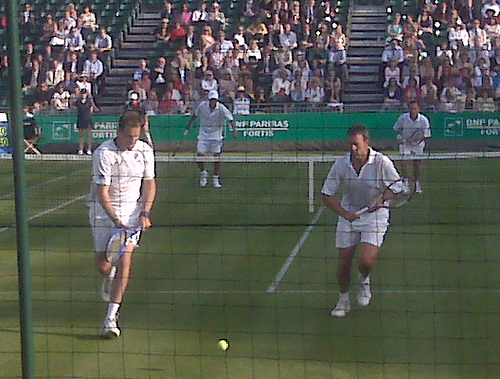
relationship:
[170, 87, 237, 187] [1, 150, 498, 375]
player on court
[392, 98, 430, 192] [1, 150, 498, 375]
player on court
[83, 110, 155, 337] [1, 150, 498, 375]
player on court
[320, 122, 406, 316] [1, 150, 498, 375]
player on court